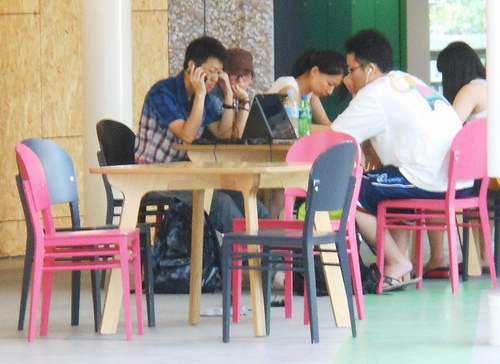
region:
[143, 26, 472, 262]
people sitting at table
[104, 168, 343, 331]
four legs under table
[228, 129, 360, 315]
pink chair under table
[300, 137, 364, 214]
back of gray chair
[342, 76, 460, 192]
white shirt on man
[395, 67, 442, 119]
design on back of shirt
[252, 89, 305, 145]
open screen of laptop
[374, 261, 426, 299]
flip flop on foot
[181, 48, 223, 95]
phone in man's hand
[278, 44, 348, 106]
girl in white shirt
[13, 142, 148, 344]
The chair is pink.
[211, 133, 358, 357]
The chair is blue.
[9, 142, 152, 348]
The chair is empty.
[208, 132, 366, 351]
The chair is not in use.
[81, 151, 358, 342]
The table is wood.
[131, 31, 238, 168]
Man is using phone.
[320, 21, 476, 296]
Man has earbuds in ear.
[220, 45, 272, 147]
Girl is wearing glasses.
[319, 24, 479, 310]
Man is wearing shirt.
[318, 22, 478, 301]
Man is wearing shorts.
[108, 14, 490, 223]
people are studing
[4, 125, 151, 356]
a blue and pink chair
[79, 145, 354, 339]
table is made of wood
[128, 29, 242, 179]
person talking by cell phone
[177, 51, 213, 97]
cell phone if black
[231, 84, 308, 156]
two laptops are open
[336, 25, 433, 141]
boy wearing white headphones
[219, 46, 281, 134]
woman wearing glasses is looking to laptop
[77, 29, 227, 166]
man is sitting on a black chair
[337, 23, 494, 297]
man is sitting on pink chair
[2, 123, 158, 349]
empty bright pink chair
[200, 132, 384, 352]
empty dark blue chair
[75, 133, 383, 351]
wooden table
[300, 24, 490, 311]
man in a white shirt wearing earbuds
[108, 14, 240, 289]
man using a cellphone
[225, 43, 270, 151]
woman resting her chin in her hand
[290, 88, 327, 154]
green plastic bottle with a blue cap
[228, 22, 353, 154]
woman looking down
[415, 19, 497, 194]
woman with long dark hair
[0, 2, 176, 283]
plywood wall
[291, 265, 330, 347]
leg of metal chair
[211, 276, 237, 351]
leg of metal chair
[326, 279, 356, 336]
leg of metal chair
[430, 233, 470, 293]
leg of metal chair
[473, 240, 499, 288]
leg of metal chair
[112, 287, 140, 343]
leg of metal chair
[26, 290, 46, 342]
leg of metal chair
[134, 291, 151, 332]
leg of metal chair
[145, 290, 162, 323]
leg of metal chair